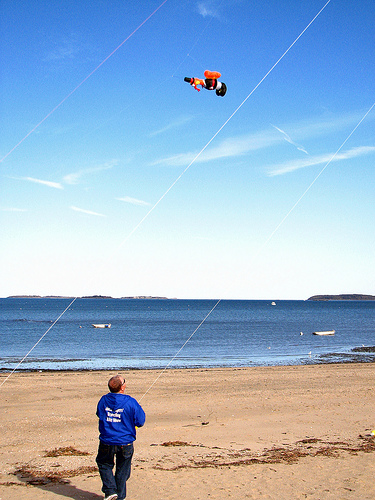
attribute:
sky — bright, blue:
[2, 1, 370, 297]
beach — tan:
[2, 366, 373, 498]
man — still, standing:
[91, 376, 148, 496]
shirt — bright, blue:
[94, 391, 147, 444]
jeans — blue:
[90, 437, 134, 499]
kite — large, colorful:
[181, 68, 230, 98]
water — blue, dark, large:
[0, 293, 371, 369]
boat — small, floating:
[312, 326, 337, 338]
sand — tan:
[192, 401, 325, 476]